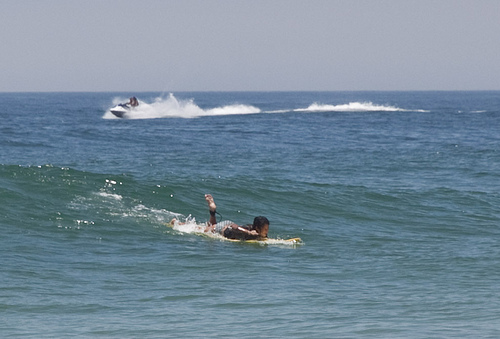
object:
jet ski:
[109, 103, 138, 119]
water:
[0, 253, 497, 338]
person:
[170, 193, 270, 241]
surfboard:
[163, 223, 301, 244]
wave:
[0, 165, 168, 214]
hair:
[246, 215, 270, 232]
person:
[129, 96, 139, 107]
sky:
[1, 1, 499, 85]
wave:
[291, 101, 430, 113]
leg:
[209, 209, 217, 224]